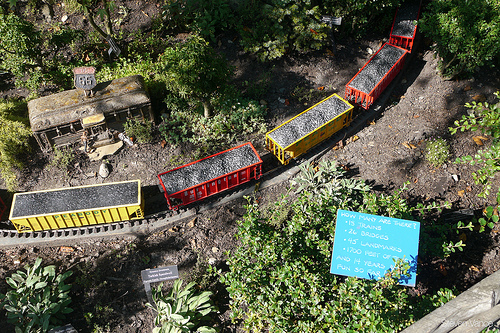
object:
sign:
[328, 204, 423, 291]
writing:
[337, 209, 418, 278]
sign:
[138, 263, 182, 286]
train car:
[7, 176, 150, 236]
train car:
[153, 136, 266, 215]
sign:
[67, 64, 102, 98]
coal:
[8, 177, 140, 220]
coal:
[158, 141, 262, 197]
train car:
[262, 88, 359, 168]